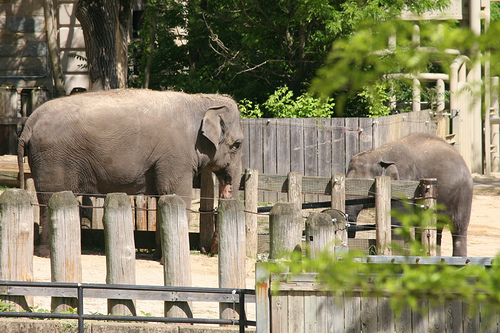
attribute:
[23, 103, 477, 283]
elephants — grey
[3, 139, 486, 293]
fence — low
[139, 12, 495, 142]
vegetation — green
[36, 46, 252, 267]
elephant — grey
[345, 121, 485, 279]
elephant — tuskless, baby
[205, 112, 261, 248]
trunk — thick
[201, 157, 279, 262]
trunk — discolored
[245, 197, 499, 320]
leaves — blurry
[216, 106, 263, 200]
eye — open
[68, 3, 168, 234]
tree — thick, brown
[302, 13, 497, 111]
branch — green, leafy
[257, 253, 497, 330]
fence — gray, light brown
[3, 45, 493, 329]
enclosure — elephant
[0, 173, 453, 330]
fence — gray, light brown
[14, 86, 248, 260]
elephant — gray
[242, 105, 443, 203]
fence — gray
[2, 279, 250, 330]
railing — metal, black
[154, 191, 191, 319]
fence post — thick, white, gray, wooden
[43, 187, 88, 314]
fence post — thick, white, gray, wooden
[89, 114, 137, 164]
skin — gray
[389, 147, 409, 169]
skin — gray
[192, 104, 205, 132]
skin — gray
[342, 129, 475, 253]
elephant — small, young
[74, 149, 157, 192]
skin — wrinkled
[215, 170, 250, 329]
post — wood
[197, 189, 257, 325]
post — brown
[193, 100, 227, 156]
elephant — ear 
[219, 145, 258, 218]
elephant — long trunk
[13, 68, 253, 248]
elephant — grey 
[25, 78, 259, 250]
elephant — hanging tail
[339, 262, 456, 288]
leaves — green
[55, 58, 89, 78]
trunk — tree , brown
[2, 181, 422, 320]
fence — wooden post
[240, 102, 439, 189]
fence — wooden post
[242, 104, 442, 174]
fence — wooden post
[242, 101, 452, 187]
fence — wooden post